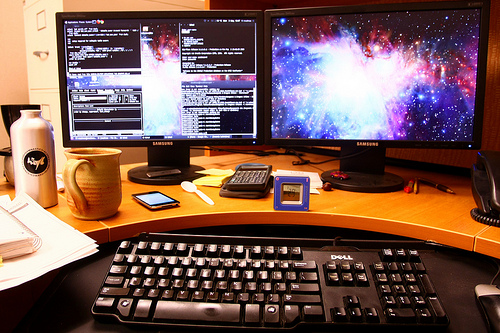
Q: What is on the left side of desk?
A: Coffee cup and travel cup.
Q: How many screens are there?
A: Two.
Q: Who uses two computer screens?
A: People who like to work on more than one thing.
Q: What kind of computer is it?
A: Dell.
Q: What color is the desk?
A: Brown.